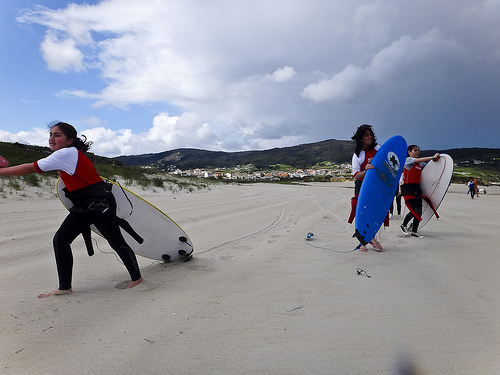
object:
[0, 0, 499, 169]
cloud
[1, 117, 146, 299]
person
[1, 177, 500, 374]
sand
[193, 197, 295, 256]
track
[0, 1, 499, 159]
sky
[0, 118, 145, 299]
people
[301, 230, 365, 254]
cord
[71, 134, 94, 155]
tail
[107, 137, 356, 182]
hills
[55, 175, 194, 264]
board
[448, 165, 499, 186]
grass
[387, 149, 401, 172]
symbol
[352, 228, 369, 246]
bottom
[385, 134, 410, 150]
top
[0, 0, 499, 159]
cloud